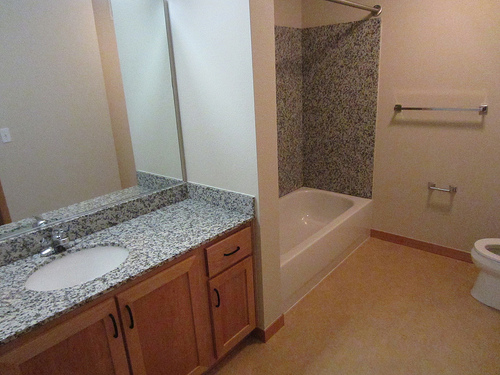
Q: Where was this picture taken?
A: Bathroom.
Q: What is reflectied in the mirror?
A: Light switch.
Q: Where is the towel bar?
A: Next to the shower.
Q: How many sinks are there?
A: One.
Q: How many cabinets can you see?
A: Three.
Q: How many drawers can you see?
A: One.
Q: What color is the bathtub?
A: White.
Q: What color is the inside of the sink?
A: White.